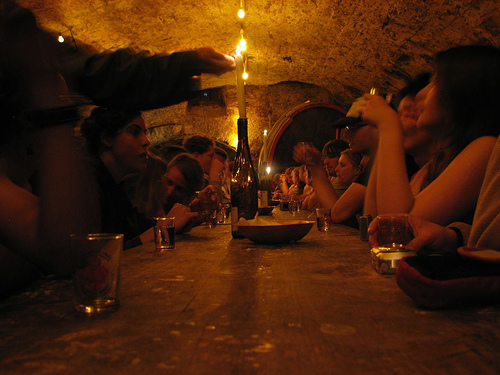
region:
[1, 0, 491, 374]
young people around a long table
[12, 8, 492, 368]
people are in a dark room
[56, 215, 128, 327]
an empty glass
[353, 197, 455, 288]
a hand holding a glass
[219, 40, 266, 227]
a candle in a bottle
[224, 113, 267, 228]
bottle is color black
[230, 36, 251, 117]
candle is lit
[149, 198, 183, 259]
a glass with white liquid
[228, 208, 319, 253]
a bowl with chips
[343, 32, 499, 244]
a woman holding a glass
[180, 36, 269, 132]
the candle is lit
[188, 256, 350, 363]
the table is brown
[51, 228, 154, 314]
the glass is empty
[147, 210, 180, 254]
the glass is halfull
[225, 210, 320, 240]
plate is on the surface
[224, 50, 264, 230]
candle is on the wine glass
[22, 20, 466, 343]
they are indoors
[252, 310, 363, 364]
the table has candle stains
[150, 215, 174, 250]
the glass has alcohol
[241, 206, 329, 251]
the plate has food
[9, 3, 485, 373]
friends in an underground party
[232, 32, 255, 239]
wine bottle holding candle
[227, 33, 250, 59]
flame of a candle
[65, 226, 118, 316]
wine glass for everyday drinking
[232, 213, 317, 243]
bowl of snacks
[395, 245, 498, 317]
bowl devoid of snacks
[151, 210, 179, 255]
glass full of beverage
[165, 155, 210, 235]
man consumed in coversation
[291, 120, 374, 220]
man clapping his hands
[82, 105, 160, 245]
woman not looking happy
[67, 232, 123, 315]
a small clear glass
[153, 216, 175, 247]
a small clear glass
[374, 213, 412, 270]
a small clear glass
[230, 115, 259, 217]
a dark wine bottle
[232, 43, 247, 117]
a lit white candle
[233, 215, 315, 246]
a small food bowl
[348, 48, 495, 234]
a woman sitting at table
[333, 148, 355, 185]
a woman's face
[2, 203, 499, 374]
a long wooden table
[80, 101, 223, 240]
a woman sitting at table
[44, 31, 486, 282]
Group of friends sitting at a table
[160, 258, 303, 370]
The table is wooden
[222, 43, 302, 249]
Lit candle on top of table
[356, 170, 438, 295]
Person is holding a glass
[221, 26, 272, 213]
Candle stuck inside a bottle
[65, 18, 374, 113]
The cave ceiling is very close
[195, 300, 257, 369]
Stain on the table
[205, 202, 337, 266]
Wooden bowl on the table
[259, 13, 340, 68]
Light reflected on the ceiling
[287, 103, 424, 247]
The friends are talking